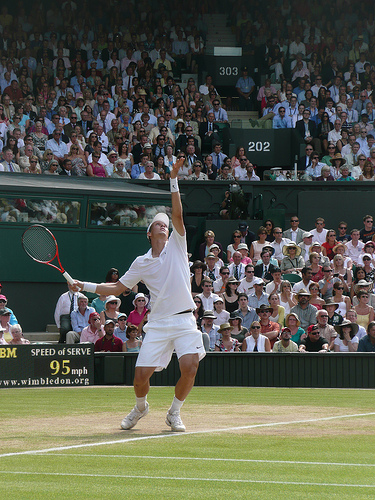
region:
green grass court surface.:
[45, 395, 108, 407]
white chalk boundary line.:
[265, 416, 351, 421]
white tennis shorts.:
[139, 330, 207, 348]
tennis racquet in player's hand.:
[22, 227, 77, 280]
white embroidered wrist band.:
[168, 176, 179, 197]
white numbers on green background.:
[244, 140, 271, 152]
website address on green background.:
[6, 377, 97, 383]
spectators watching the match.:
[242, 237, 321, 339]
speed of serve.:
[49, 356, 88, 375]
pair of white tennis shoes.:
[128, 410, 179, 429]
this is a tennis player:
[9, 154, 190, 435]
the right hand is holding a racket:
[3, 224, 117, 303]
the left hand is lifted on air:
[167, 154, 193, 225]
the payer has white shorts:
[151, 320, 190, 348]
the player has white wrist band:
[81, 280, 99, 289]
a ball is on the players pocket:
[192, 330, 205, 341]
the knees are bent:
[128, 354, 198, 396]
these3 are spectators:
[208, 227, 368, 347]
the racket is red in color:
[16, 223, 82, 291]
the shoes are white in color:
[164, 415, 184, 428]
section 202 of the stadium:
[214, 123, 315, 174]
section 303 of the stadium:
[208, 46, 257, 79]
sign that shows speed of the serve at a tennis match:
[25, 345, 103, 388]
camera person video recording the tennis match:
[197, 176, 274, 226]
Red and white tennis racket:
[19, 216, 81, 298]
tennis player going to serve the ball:
[22, 125, 214, 434]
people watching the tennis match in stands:
[219, 257, 366, 344]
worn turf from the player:
[19, 398, 361, 447]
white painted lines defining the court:
[2, 429, 232, 497]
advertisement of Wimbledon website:
[1, 377, 104, 388]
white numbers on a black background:
[243, 135, 283, 154]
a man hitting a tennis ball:
[32, 117, 265, 438]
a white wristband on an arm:
[76, 281, 108, 291]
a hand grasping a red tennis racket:
[67, 272, 88, 298]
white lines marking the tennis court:
[173, 450, 260, 491]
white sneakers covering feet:
[109, 407, 190, 437]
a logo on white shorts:
[193, 341, 206, 351]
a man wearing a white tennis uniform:
[125, 201, 205, 439]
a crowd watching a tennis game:
[203, 238, 361, 335]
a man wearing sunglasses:
[218, 265, 235, 280]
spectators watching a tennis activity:
[0, 2, 372, 497]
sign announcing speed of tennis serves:
[3, 342, 96, 390]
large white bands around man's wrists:
[79, 171, 184, 301]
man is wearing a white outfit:
[112, 225, 208, 367]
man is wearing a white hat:
[141, 205, 167, 238]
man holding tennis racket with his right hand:
[17, 214, 95, 295]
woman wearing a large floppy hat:
[276, 237, 303, 267]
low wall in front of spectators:
[84, 318, 369, 387]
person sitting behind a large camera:
[210, 180, 264, 226]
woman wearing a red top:
[320, 229, 340, 259]